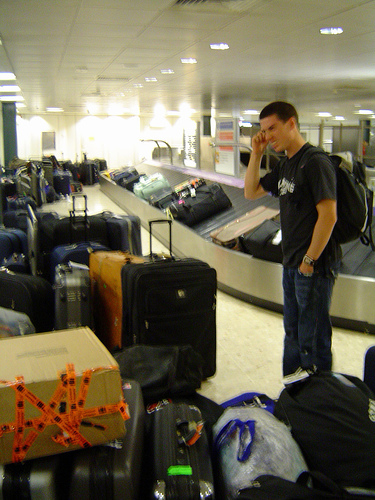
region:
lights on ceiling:
[122, 33, 232, 103]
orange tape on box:
[1, 361, 134, 467]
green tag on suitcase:
[163, 459, 195, 480]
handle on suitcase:
[139, 210, 181, 263]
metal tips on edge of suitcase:
[147, 476, 216, 499]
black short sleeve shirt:
[258, 140, 346, 274]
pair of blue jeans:
[275, 251, 337, 376]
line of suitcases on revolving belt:
[101, 160, 234, 231]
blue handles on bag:
[204, 385, 284, 465]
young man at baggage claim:
[13, 9, 362, 464]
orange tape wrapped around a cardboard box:
[1, 357, 121, 448]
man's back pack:
[307, 142, 368, 240]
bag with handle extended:
[143, 213, 173, 273]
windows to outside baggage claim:
[20, 110, 144, 164]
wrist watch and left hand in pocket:
[292, 250, 313, 295]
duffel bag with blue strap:
[213, 390, 295, 483]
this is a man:
[233, 77, 368, 393]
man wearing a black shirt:
[225, 143, 346, 269]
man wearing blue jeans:
[258, 237, 354, 376]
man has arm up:
[223, 111, 292, 215]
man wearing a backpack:
[313, 136, 370, 262]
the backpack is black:
[325, 144, 374, 255]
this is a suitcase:
[94, 190, 244, 402]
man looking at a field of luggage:
[2, 90, 350, 481]